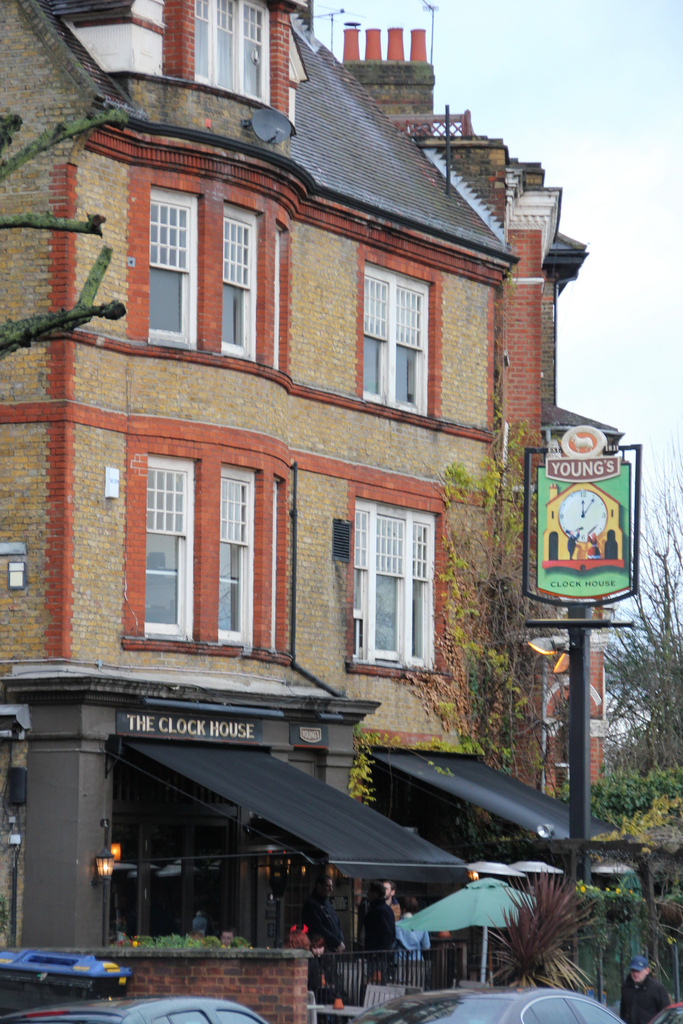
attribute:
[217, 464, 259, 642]
window — glass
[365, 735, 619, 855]
awning — black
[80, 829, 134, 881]
lights — on 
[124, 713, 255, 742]
text — white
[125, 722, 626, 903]
awnings — black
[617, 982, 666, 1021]
shirt — black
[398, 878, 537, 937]
umbrella — open, green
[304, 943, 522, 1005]
railing — black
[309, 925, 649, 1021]
railing — black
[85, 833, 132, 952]
light fixture — black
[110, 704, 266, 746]
sign — the clock house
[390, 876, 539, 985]
umbrella — green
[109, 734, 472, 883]
awning — black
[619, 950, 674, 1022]
man — walking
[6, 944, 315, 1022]
wall — brick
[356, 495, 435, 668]
window — white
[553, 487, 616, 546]
clock — picture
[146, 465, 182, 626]
glass — clean, clear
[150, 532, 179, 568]
glass — clear, clean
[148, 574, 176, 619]
glass — clean, clear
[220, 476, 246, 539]
glass — clear, clean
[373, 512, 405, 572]
glass — clean, clear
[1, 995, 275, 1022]
car — parked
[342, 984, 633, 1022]
car — parked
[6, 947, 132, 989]
lid — blue, yellow